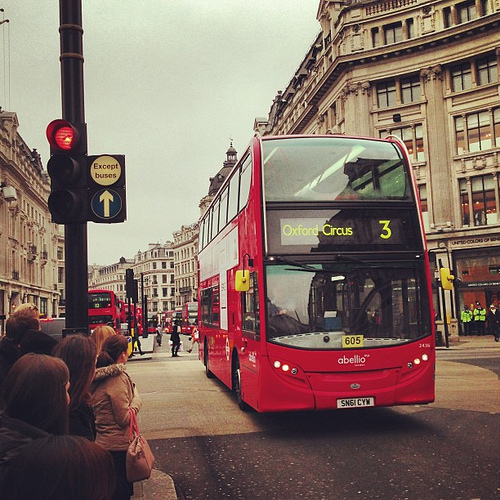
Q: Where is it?
A: This is at the road.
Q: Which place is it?
A: It is a road.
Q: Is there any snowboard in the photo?
A: No, there are no snowboards.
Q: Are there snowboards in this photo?
A: No, there are no snowboards.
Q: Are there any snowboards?
A: No, there are no snowboards.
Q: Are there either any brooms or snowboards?
A: No, there are no snowboards or brooms.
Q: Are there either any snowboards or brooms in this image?
A: No, there are no snowboards or brooms.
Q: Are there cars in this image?
A: No, there are no cars.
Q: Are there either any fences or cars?
A: No, there are no cars or fences.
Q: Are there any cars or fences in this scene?
A: No, there are no cars or fences.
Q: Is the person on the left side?
A: Yes, the person is on the left of the image.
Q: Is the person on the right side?
A: No, the person is on the left of the image.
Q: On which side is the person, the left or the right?
A: The person is on the left of the image.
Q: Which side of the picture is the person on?
A: The person is on the left of the image.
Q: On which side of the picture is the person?
A: The person is on the left of the image.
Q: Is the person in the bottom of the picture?
A: Yes, the person is in the bottom of the image.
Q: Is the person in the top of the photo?
A: No, the person is in the bottom of the image.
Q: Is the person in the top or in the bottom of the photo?
A: The person is in the bottom of the image.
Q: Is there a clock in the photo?
A: No, there are no clocks.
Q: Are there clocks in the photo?
A: No, there are no clocks.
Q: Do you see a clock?
A: No, there are no clocks.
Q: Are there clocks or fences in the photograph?
A: No, there are no clocks or fences.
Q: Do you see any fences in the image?
A: No, there are no fences.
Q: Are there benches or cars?
A: No, there are no cars or benches.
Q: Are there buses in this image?
A: Yes, there are buses.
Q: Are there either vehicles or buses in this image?
A: Yes, there are buses.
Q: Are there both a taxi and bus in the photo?
A: No, there are buses but no taxis.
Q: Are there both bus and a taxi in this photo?
A: No, there are buses but no taxis.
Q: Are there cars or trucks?
A: No, there are no cars or trucks.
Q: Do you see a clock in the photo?
A: No, there are no clocks.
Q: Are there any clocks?
A: No, there are no clocks.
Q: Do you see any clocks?
A: No, there are no clocks.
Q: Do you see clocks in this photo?
A: No, there are no clocks.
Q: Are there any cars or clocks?
A: No, there are no clocks or cars.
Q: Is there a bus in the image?
A: Yes, there is a bus.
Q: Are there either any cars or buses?
A: Yes, there is a bus.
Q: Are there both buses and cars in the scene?
A: No, there is a bus but no cars.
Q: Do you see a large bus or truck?
A: Yes, there is a large bus.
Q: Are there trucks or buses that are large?
A: Yes, the bus is large.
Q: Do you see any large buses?
A: Yes, there is a large bus.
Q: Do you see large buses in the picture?
A: Yes, there is a large bus.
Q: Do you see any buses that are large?
A: Yes, there is a bus that is large.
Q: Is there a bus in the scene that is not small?
A: Yes, there is a large bus.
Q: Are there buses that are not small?
A: Yes, there is a large bus.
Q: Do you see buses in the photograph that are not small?
A: Yes, there is a large bus.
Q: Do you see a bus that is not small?
A: Yes, there is a large bus.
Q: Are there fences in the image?
A: No, there are no fences.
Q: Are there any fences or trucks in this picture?
A: No, there are no fences or trucks.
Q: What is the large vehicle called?
A: The vehicle is a bus.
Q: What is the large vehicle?
A: The vehicle is a bus.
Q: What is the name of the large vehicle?
A: The vehicle is a bus.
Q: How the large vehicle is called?
A: The vehicle is a bus.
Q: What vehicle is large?
A: The vehicle is a bus.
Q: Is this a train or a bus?
A: This is a bus.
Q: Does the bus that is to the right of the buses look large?
A: Yes, the bus is large.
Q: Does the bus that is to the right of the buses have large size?
A: Yes, the bus is large.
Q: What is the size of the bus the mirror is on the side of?
A: The bus is large.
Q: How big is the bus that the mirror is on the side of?
A: The bus is large.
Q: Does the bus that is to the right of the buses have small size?
A: No, the bus is large.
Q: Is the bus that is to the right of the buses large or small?
A: The bus is large.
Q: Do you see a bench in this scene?
A: No, there are no benches.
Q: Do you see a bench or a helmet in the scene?
A: No, there are no benches or helmets.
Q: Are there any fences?
A: No, there are no fences.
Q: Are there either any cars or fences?
A: No, there are no fences or cars.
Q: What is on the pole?
A: The sign is on the pole.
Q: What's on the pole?
A: The sign is on the pole.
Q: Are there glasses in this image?
A: No, there are no glasses.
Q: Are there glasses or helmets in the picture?
A: No, there are no glasses or helmets.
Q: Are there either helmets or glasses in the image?
A: No, there are no glasses or helmets.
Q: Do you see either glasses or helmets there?
A: No, there are no glasses or helmets.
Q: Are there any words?
A: Yes, there are words.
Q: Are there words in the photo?
A: Yes, there are words.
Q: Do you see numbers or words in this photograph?
A: Yes, there are words.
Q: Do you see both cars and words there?
A: No, there are words but no cars.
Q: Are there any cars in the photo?
A: No, there are no cars.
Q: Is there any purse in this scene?
A: Yes, there is a purse.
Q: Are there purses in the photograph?
A: Yes, there is a purse.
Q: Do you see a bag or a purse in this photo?
A: Yes, there is a purse.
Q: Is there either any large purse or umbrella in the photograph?
A: Yes, there is a large purse.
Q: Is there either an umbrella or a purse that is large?
A: Yes, the purse is large.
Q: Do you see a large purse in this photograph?
A: Yes, there is a large purse.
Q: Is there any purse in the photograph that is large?
A: Yes, there is a purse that is large.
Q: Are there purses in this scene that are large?
A: Yes, there is a purse that is large.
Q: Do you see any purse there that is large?
A: Yes, there is a purse that is large.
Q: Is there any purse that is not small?
A: Yes, there is a large purse.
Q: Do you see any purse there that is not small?
A: Yes, there is a large purse.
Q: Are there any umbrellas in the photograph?
A: No, there are no umbrellas.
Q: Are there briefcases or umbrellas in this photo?
A: No, there are no umbrellas or briefcases.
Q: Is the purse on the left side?
A: Yes, the purse is on the left of the image.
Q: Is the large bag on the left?
A: Yes, the purse is on the left of the image.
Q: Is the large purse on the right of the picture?
A: No, the purse is on the left of the image.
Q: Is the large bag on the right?
A: No, the purse is on the left of the image.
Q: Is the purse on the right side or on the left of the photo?
A: The purse is on the left of the image.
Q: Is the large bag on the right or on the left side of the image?
A: The purse is on the left of the image.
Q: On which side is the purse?
A: The purse is on the left of the image.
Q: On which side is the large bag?
A: The purse is on the left of the image.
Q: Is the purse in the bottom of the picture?
A: Yes, the purse is in the bottom of the image.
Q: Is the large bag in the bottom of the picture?
A: Yes, the purse is in the bottom of the image.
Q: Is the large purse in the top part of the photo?
A: No, the purse is in the bottom of the image.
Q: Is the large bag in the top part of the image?
A: No, the purse is in the bottom of the image.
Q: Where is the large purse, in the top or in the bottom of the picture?
A: The purse is in the bottom of the image.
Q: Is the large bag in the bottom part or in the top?
A: The purse is in the bottom of the image.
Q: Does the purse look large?
A: Yes, the purse is large.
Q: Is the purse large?
A: Yes, the purse is large.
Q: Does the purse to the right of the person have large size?
A: Yes, the purse is large.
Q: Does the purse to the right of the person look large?
A: Yes, the purse is large.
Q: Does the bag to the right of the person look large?
A: Yes, the purse is large.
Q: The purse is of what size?
A: The purse is large.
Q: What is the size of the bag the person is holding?
A: The purse is large.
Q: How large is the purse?
A: The purse is large.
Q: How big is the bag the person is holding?
A: The purse is large.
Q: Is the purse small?
A: No, the purse is large.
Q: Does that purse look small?
A: No, the purse is large.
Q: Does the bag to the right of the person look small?
A: No, the purse is large.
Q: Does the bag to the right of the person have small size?
A: No, the purse is large.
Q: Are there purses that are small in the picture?
A: No, there is a purse but it is large.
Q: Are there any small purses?
A: No, there is a purse but it is large.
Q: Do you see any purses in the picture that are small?
A: No, there is a purse but it is large.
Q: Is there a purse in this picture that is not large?
A: No, there is a purse but it is large.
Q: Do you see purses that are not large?
A: No, there is a purse but it is large.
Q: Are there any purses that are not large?
A: No, there is a purse but it is large.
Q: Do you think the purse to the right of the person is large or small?
A: The purse is large.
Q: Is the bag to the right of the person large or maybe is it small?
A: The purse is large.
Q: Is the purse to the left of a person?
A: No, the purse is to the right of a person.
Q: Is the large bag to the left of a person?
A: No, the purse is to the right of a person.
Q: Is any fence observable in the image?
A: No, there are no fences.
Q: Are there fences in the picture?
A: No, there are no fences.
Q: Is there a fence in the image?
A: No, there are no fences.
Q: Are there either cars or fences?
A: No, there are no fences or cars.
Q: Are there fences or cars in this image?
A: No, there are no fences or cars.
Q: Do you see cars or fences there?
A: No, there are no fences or cars.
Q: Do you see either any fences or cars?
A: No, there are no fences or cars.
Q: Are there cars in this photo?
A: No, there are no cars.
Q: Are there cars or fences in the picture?
A: No, there are no cars or fences.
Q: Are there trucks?
A: No, there are no trucks.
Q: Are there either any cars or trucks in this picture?
A: No, there are no trucks or cars.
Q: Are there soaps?
A: No, there are no soaps.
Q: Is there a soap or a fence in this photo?
A: No, there are no soaps or fences.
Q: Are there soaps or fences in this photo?
A: No, there are no soaps or fences.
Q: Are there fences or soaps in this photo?
A: No, there are no soaps or fences.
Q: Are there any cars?
A: No, there are no cars.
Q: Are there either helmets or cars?
A: No, there are no cars or helmets.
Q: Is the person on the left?
A: Yes, the person is on the left of the image.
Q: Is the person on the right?
A: No, the person is on the left of the image.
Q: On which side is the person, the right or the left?
A: The person is on the left of the image.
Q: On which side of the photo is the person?
A: The person is on the left of the image.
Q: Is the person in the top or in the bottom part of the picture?
A: The person is in the bottom of the image.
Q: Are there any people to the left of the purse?
A: Yes, there is a person to the left of the purse.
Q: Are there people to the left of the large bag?
A: Yes, there is a person to the left of the purse.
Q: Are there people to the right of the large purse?
A: No, the person is to the left of the purse.